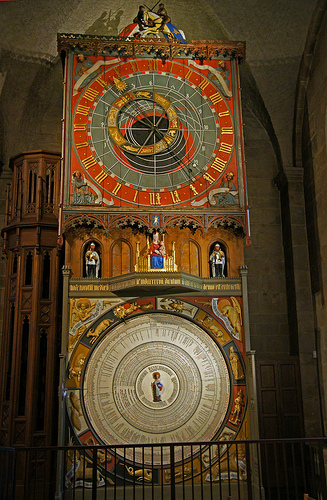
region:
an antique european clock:
[53, 0, 249, 496]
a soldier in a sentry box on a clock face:
[79, 237, 100, 278]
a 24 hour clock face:
[69, 49, 238, 209]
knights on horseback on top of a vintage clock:
[114, 1, 187, 48]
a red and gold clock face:
[74, 56, 236, 207]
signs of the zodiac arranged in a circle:
[64, 297, 250, 485]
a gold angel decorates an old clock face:
[69, 298, 104, 339]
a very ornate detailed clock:
[51, 27, 263, 498]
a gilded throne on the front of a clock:
[133, 229, 178, 274]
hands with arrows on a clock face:
[98, 62, 205, 179]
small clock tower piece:
[58, 35, 243, 418]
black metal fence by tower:
[43, 439, 293, 496]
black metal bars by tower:
[25, 439, 205, 499]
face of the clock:
[67, 60, 226, 204]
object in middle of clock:
[140, 368, 166, 405]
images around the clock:
[43, 301, 144, 380]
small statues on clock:
[83, 232, 231, 279]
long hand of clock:
[116, 76, 172, 142]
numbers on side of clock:
[203, 79, 233, 185]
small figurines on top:
[131, 0, 181, 49]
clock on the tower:
[85, 55, 246, 200]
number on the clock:
[187, 183, 206, 200]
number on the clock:
[200, 170, 214, 186]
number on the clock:
[206, 155, 226, 176]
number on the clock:
[131, 189, 143, 202]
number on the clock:
[92, 173, 113, 185]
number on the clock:
[79, 151, 99, 172]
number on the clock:
[68, 136, 87, 152]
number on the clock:
[209, 108, 231, 127]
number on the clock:
[198, 72, 208, 86]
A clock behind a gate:
[53, 6, 266, 299]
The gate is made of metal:
[40, 438, 311, 498]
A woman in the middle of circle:
[146, 364, 170, 405]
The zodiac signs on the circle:
[64, 302, 256, 486]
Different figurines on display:
[80, 226, 233, 280]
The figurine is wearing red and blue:
[147, 228, 169, 268]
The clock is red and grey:
[73, 134, 141, 181]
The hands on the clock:
[103, 78, 189, 166]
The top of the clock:
[127, 2, 184, 35]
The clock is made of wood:
[58, 36, 254, 427]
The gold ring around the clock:
[109, 89, 178, 154]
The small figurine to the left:
[79, 233, 118, 285]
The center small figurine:
[146, 231, 175, 281]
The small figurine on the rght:
[202, 248, 230, 281]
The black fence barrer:
[0, 435, 321, 485]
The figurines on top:
[126, 3, 183, 49]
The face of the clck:
[75, 59, 243, 214]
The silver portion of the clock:
[81, 308, 271, 487]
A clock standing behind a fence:
[71, 38, 261, 492]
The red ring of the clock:
[75, 74, 248, 206]